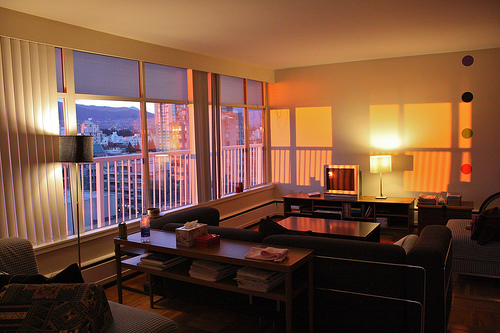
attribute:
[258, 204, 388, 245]
table — coffee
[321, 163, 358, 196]
television — turned off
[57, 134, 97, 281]
floor lamp — turned on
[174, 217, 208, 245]
box of tissues — open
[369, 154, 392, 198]
lamp — turned on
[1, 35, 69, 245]
blinds — opened, white, beige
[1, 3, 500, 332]
apartment — pictured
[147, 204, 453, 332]
sofa — modern looking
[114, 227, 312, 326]
table — wooden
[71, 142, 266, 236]
railing — metal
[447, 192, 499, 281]
chair — gray